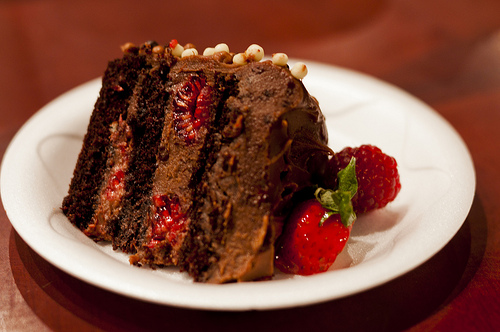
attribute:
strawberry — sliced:
[279, 155, 357, 275]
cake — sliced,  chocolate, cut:
[62, 39, 335, 284]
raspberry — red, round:
[328, 144, 402, 215]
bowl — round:
[1, 52, 477, 312]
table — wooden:
[1, 1, 498, 330]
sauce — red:
[172, 75, 210, 143]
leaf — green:
[312, 156, 359, 227]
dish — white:
[1, 51, 478, 310]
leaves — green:
[314, 153, 358, 227]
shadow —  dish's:
[9, 191, 487, 331]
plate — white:
[1, 55, 479, 313]